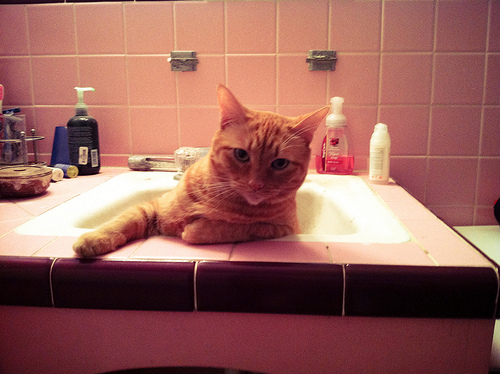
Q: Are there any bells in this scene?
A: No, there are no bells.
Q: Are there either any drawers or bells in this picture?
A: No, there are no bells or drawers.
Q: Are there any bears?
A: No, there are no bears.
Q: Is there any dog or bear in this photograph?
A: No, there are no bears or dogs.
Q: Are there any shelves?
A: No, there are no shelves.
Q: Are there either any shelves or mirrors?
A: No, there are no shelves or mirrors.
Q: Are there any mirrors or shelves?
A: No, there are no shelves or mirrors.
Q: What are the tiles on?
A: The tiles are on the wall.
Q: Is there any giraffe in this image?
A: No, there are no giraffes.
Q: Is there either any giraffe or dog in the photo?
A: No, there are no giraffes or dogs.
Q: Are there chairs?
A: No, there are no chairs.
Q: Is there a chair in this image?
A: No, there are no chairs.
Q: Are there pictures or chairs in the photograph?
A: No, there are no chairs or pictures.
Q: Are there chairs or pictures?
A: No, there are no chairs or pictures.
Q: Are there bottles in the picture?
A: Yes, there is a bottle.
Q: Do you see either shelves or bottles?
A: Yes, there is a bottle.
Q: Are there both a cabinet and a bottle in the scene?
A: No, there is a bottle but no cabinets.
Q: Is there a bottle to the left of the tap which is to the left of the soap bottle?
A: Yes, there is a bottle to the left of the tap.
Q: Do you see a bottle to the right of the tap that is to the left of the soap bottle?
A: No, the bottle is to the left of the faucet.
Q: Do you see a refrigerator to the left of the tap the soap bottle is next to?
A: No, there is a bottle to the left of the faucet.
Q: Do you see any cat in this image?
A: Yes, there is a cat.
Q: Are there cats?
A: Yes, there is a cat.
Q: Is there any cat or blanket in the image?
A: Yes, there is a cat.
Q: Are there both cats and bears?
A: No, there is a cat but no bears.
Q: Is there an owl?
A: No, there are no owls.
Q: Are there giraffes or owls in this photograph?
A: No, there are no owls or giraffes.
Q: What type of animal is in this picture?
A: The animal is a cat.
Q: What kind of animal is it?
A: The animal is a cat.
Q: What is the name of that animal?
A: This is a cat.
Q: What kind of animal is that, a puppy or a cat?
A: This is a cat.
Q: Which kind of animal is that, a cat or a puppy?
A: This is a cat.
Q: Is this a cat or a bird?
A: This is a cat.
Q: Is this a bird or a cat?
A: This is a cat.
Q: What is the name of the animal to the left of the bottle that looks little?
A: The animal is a cat.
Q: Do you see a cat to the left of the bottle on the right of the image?
A: Yes, there is a cat to the left of the bottle.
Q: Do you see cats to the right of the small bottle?
A: No, the cat is to the left of the bottle.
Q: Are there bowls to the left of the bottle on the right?
A: No, there is a cat to the left of the bottle.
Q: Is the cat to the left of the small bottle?
A: Yes, the cat is to the left of the bottle.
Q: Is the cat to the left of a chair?
A: No, the cat is to the left of the bottle.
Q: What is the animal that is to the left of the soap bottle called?
A: The animal is a cat.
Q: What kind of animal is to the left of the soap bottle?
A: The animal is a cat.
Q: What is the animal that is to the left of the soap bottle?
A: The animal is a cat.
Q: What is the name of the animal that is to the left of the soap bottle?
A: The animal is a cat.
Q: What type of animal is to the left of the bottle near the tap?
A: The animal is a cat.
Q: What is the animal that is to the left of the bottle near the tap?
A: The animal is a cat.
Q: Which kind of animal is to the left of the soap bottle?
A: The animal is a cat.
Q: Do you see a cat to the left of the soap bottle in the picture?
A: Yes, there is a cat to the left of the soap bottle.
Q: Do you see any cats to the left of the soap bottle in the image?
A: Yes, there is a cat to the left of the soap bottle.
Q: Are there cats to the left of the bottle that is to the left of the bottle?
A: Yes, there is a cat to the left of the soap bottle.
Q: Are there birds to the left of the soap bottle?
A: No, there is a cat to the left of the soap bottle.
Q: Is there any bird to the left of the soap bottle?
A: No, there is a cat to the left of the soap bottle.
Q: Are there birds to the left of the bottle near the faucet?
A: No, there is a cat to the left of the soap bottle.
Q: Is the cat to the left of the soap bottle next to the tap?
A: Yes, the cat is to the left of the soap bottle.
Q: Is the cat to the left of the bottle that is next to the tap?
A: Yes, the cat is to the left of the soap bottle.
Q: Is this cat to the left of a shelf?
A: No, the cat is to the left of the soap bottle.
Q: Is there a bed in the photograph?
A: No, there are no beds.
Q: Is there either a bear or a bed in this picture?
A: No, there are no beds or bears.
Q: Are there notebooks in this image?
A: No, there are no notebooks.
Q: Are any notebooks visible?
A: No, there are no notebooks.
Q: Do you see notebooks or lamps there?
A: No, there are no notebooks or lamps.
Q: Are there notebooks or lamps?
A: No, there are no notebooks or lamps.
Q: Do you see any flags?
A: No, there are no flags.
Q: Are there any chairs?
A: No, there are no chairs.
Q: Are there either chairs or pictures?
A: No, there are no chairs or pictures.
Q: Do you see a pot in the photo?
A: No, there are no pots.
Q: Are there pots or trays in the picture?
A: No, there are no pots or trays.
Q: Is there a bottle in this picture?
A: Yes, there is a bottle.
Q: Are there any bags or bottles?
A: Yes, there is a bottle.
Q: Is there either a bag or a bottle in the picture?
A: Yes, there is a bottle.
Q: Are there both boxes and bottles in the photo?
A: No, there is a bottle but no boxes.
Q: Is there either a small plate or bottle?
A: Yes, there is a small bottle.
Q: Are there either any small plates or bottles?
A: Yes, there is a small bottle.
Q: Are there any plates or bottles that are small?
A: Yes, the bottle is small.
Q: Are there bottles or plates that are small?
A: Yes, the bottle is small.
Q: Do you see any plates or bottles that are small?
A: Yes, the bottle is small.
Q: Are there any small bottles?
A: Yes, there is a small bottle.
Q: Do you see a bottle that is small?
A: Yes, there is a bottle that is small.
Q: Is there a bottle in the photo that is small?
A: Yes, there is a bottle that is small.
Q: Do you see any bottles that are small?
A: Yes, there is a bottle that is small.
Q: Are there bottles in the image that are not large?
A: Yes, there is a small bottle.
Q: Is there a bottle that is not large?
A: Yes, there is a small bottle.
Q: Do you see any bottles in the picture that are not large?
A: Yes, there is a small bottle.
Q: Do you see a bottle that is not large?
A: Yes, there is a small bottle.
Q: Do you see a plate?
A: No, there are no plates.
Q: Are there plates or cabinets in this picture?
A: No, there are no plates or cabinets.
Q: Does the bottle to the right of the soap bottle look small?
A: Yes, the bottle is small.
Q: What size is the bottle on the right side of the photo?
A: The bottle is small.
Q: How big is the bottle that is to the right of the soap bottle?
A: The bottle is small.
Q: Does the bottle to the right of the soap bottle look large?
A: No, the bottle is small.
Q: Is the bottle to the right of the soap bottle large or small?
A: The bottle is small.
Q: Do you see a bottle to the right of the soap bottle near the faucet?
A: Yes, there is a bottle to the right of the soap bottle.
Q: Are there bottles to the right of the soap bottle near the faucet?
A: Yes, there is a bottle to the right of the soap bottle.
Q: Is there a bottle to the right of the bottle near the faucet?
A: Yes, there is a bottle to the right of the soap bottle.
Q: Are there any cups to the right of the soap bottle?
A: No, there is a bottle to the right of the soap bottle.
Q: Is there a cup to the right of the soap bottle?
A: No, there is a bottle to the right of the soap bottle.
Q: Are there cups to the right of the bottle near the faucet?
A: No, there is a bottle to the right of the soap bottle.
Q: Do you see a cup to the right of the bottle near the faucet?
A: No, there is a bottle to the right of the soap bottle.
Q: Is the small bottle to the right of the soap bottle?
A: Yes, the bottle is to the right of the soap bottle.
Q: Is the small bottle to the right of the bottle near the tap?
A: Yes, the bottle is to the right of the soap bottle.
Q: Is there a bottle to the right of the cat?
A: Yes, there is a bottle to the right of the cat.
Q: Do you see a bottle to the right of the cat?
A: Yes, there is a bottle to the right of the cat.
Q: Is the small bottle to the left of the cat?
A: No, the bottle is to the right of the cat.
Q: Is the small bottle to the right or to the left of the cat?
A: The bottle is to the right of the cat.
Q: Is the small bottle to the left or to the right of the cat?
A: The bottle is to the right of the cat.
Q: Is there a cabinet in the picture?
A: No, there are no cabinets.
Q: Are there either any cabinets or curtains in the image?
A: No, there are no cabinets or curtains.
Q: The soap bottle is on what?
A: The soap bottle is on the counter.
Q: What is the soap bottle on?
A: The soap bottle is on the counter.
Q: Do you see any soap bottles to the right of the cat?
A: Yes, there is a soap bottle to the right of the cat.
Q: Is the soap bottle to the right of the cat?
A: Yes, the soap bottle is to the right of the cat.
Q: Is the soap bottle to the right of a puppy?
A: No, the soap bottle is to the right of the cat.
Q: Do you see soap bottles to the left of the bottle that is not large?
A: Yes, there is a soap bottle to the left of the bottle.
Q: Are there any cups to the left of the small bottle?
A: No, there is a soap bottle to the left of the bottle.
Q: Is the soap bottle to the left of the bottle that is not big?
A: Yes, the soap bottle is to the left of the bottle.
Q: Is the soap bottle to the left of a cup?
A: No, the soap bottle is to the left of the bottle.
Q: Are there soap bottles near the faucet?
A: Yes, there is a soap bottle near the faucet.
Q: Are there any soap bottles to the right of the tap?
A: Yes, there is a soap bottle to the right of the tap.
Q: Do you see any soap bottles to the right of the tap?
A: Yes, there is a soap bottle to the right of the tap.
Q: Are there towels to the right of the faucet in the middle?
A: No, there is a soap bottle to the right of the tap.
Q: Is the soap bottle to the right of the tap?
A: Yes, the soap bottle is to the right of the tap.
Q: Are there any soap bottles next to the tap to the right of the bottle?
A: Yes, there is a soap bottle next to the tap.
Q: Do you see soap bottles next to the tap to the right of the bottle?
A: Yes, there is a soap bottle next to the tap.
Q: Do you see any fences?
A: No, there are no fences.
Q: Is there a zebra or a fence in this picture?
A: No, there are no fences or zebras.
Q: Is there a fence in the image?
A: No, there are no fences.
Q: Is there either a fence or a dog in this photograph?
A: No, there are no fences or dogs.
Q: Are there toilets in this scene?
A: No, there are no toilets.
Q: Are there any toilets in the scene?
A: No, there are no toilets.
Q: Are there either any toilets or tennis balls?
A: No, there are no toilets or tennis balls.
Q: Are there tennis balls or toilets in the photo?
A: No, there are no toilets or tennis balls.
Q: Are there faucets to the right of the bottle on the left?
A: Yes, there is a faucet to the right of the bottle.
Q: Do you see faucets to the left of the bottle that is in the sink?
A: No, the faucet is to the right of the bottle.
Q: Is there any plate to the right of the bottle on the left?
A: No, there is a faucet to the right of the bottle.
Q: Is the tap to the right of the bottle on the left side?
A: Yes, the tap is to the right of the bottle.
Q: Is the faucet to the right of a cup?
A: No, the faucet is to the right of the bottle.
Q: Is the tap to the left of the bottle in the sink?
A: No, the tap is to the right of the bottle.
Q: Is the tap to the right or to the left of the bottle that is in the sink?
A: The tap is to the right of the bottle.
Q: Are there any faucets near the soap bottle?
A: Yes, there is a faucet near the soap bottle.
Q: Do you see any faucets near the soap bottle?
A: Yes, there is a faucet near the soap bottle.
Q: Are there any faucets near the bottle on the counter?
A: Yes, there is a faucet near the soap bottle.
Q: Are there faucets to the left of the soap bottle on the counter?
A: Yes, there is a faucet to the left of the soap bottle.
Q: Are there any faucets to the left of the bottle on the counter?
A: Yes, there is a faucet to the left of the soap bottle.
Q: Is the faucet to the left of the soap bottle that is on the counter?
A: Yes, the faucet is to the left of the soap bottle.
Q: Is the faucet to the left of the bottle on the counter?
A: Yes, the faucet is to the left of the soap bottle.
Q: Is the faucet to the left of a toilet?
A: No, the faucet is to the left of the soap bottle.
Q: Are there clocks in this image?
A: No, there are no clocks.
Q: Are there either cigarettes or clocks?
A: No, there are no clocks or cigarettes.